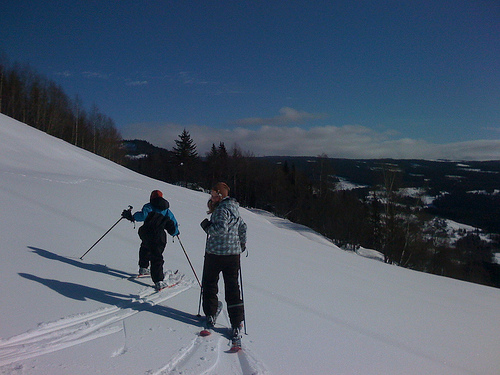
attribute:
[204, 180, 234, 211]
hat — brown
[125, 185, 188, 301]
boy — small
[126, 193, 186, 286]
skier — black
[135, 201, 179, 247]
jacket — blue, black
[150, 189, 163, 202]
hat — orange.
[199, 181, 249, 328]
girl — looking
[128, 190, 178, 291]
kid — skiing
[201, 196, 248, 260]
jacket — plaid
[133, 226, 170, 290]
pants — black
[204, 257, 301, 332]
pants — black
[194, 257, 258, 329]
pants — black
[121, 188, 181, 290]
kid — skiing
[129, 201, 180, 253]
jacket — black, blue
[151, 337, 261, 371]
prints — ski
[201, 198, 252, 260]
jacket — blue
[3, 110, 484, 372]
snow — untouched, white